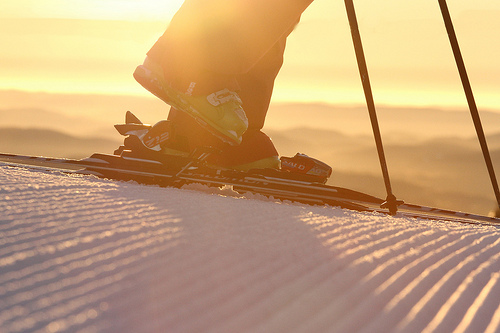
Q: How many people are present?
A: One.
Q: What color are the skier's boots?
A: Green.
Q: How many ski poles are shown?
A: Two.